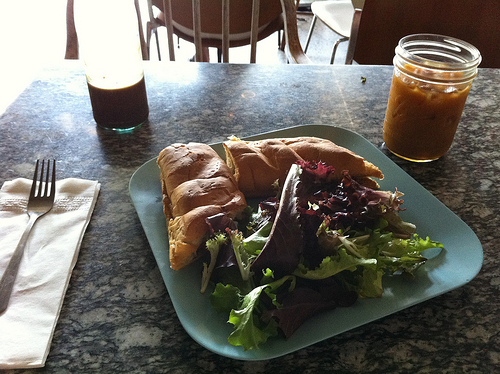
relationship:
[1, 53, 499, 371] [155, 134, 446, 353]
table with food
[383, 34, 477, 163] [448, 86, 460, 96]
beverage has ice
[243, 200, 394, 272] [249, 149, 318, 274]
salad with lettuce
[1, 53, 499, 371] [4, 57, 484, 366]
table with top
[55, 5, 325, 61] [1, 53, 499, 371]
chair on other side of table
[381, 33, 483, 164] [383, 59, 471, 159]
container full with a beverage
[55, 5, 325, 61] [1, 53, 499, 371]
chair next to table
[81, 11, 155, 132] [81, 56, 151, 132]
container with salad dressing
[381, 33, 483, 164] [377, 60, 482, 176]
container with dressing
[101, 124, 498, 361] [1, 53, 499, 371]
plate on table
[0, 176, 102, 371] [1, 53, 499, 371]
napkin on table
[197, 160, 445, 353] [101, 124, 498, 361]
salad on plate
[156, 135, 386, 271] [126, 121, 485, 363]
sandwich on plate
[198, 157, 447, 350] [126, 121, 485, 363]
lettuce on plate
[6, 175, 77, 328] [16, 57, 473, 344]
napkin on table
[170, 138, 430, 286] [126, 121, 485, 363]
food on a plate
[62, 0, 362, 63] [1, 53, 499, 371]
chair next to table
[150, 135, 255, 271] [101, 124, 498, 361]
sandwich on a plate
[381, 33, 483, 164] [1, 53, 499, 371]
container on a table